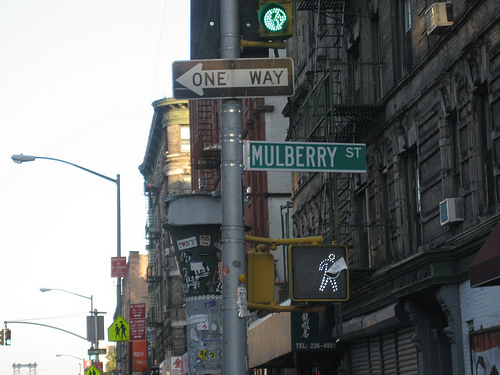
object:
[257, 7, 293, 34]
traffic light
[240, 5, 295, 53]
yellow sign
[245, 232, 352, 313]
yellow sign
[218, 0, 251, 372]
gray pole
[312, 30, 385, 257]
fire escape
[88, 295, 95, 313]
pole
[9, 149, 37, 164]
street light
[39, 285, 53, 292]
street light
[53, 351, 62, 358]
street light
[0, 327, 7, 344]
traffic light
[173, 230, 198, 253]
sticker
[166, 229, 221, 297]
metal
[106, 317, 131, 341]
sign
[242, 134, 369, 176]
signs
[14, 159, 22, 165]
light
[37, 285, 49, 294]
light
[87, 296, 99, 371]
pole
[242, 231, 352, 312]
yellow traffic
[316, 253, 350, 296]
traffic light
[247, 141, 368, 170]
green sign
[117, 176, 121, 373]
pole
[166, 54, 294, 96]
traffic sign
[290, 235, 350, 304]
traffic sign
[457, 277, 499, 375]
paint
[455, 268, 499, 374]
wall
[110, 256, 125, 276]
sign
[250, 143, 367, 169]
letters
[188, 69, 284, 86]
letters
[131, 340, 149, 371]
letters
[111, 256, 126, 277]
letters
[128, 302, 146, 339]
sign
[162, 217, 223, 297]
post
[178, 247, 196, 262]
stickers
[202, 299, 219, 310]
stickers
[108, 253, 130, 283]
red sign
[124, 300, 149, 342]
red sign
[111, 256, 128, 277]
white lettering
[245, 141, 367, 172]
white lettering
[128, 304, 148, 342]
white lettering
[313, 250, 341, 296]
signals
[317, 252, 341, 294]
crossing sign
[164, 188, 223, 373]
structure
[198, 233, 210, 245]
sticker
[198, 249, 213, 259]
sticker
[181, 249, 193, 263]
sticker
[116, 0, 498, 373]
buildings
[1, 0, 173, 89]
blue sky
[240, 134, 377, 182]
sign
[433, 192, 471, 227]
air conditioner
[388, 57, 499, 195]
wall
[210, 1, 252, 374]
pole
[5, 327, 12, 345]
signal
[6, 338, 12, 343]
light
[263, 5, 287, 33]
light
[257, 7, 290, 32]
signal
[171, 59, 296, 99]
sign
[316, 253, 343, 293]
light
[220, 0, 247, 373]
sign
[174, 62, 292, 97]
arrow